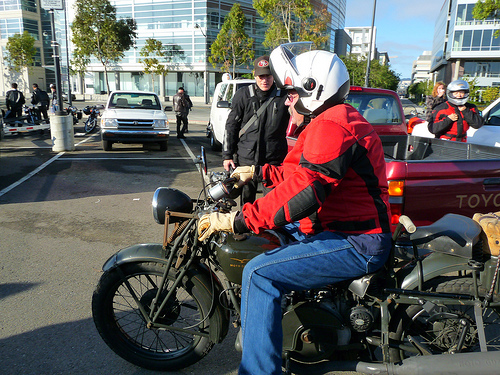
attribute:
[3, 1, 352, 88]
building — wide, white, tall, big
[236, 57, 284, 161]
man — watching, looking, white, old, standing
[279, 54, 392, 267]
man — older, sitting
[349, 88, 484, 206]
pickup — red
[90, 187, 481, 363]
motorcycle — big, black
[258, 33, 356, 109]
helmet — white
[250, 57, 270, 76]
baseball cap — black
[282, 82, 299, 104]
sunglasses — red